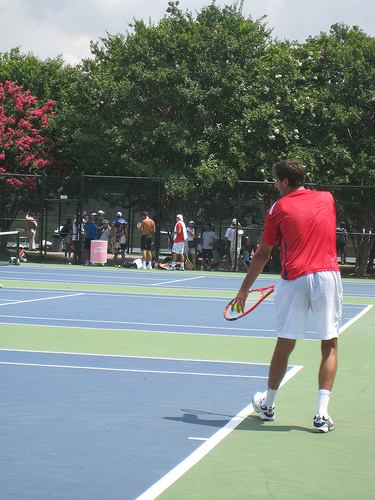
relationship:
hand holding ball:
[230, 291, 246, 314] [232, 303, 240, 311]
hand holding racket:
[230, 291, 246, 314] [227, 287, 280, 323]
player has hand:
[239, 152, 344, 424] [230, 291, 246, 314]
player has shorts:
[239, 152, 344, 424] [273, 272, 340, 343]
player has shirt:
[239, 152, 344, 424] [266, 190, 341, 277]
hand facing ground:
[230, 291, 246, 314] [29, 276, 341, 459]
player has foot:
[239, 152, 344, 424] [253, 379, 275, 425]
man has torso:
[138, 212, 156, 267] [136, 219, 154, 238]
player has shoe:
[239, 152, 344, 424] [253, 388, 275, 418]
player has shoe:
[239, 152, 344, 424] [310, 412, 333, 432]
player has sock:
[239, 152, 344, 424] [264, 387, 278, 407]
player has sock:
[239, 152, 344, 424] [317, 391, 329, 416]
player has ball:
[239, 152, 344, 424] [232, 303, 240, 311]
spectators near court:
[66, 207, 245, 267] [21, 356, 224, 451]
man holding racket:
[138, 212, 156, 267] [227, 287, 280, 323]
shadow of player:
[166, 409, 321, 436] [239, 152, 344, 424]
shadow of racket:
[166, 409, 321, 436] [227, 287, 280, 323]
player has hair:
[239, 152, 344, 424] [272, 160, 308, 186]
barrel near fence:
[88, 237, 111, 264] [53, 174, 246, 266]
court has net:
[21, 356, 224, 451] [1, 228, 25, 266]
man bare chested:
[138, 212, 156, 267] [135, 217, 157, 235]